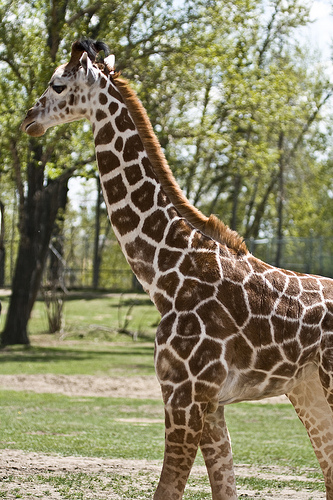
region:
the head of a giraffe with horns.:
[16, 17, 153, 145]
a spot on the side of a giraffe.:
[186, 336, 224, 375]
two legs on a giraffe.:
[137, 377, 239, 498]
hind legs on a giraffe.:
[281, 366, 331, 498]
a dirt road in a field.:
[0, 370, 331, 405]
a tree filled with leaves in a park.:
[2, 0, 221, 349]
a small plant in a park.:
[14, 264, 82, 381]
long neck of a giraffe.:
[89, 121, 177, 289]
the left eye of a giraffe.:
[49, 81, 75, 97]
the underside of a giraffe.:
[207, 378, 302, 416]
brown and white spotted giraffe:
[18, 34, 330, 496]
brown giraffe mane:
[105, 71, 251, 254]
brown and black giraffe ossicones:
[64, 36, 107, 68]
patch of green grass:
[41, 399, 80, 430]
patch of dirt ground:
[82, 375, 128, 394]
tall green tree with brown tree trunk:
[2, 1, 201, 347]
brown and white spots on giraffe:
[187, 270, 272, 351]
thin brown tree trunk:
[269, 173, 289, 260]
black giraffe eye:
[47, 81, 73, 97]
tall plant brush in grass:
[39, 282, 69, 338]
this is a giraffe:
[14, 26, 331, 487]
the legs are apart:
[225, 391, 329, 459]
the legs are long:
[150, 421, 243, 497]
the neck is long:
[83, 104, 222, 261]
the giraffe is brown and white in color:
[172, 369, 207, 408]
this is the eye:
[50, 79, 65, 99]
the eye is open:
[51, 81, 69, 96]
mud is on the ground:
[47, 459, 107, 499]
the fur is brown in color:
[216, 229, 250, 242]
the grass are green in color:
[82, 422, 119, 444]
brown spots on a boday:
[160, 237, 201, 287]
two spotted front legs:
[159, 420, 239, 494]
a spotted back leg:
[294, 412, 331, 442]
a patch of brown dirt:
[24, 374, 154, 397]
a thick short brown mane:
[135, 112, 151, 134]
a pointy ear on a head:
[80, 50, 104, 86]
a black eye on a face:
[51, 80, 81, 98]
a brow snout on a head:
[20, 112, 41, 138]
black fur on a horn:
[77, 39, 97, 55]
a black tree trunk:
[15, 228, 41, 336]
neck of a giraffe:
[102, 153, 147, 182]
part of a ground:
[88, 461, 133, 497]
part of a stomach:
[239, 367, 276, 407]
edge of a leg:
[214, 446, 235, 482]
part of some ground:
[88, 423, 120, 444]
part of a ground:
[85, 462, 117, 488]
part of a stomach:
[248, 339, 272, 366]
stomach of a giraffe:
[269, 281, 310, 352]